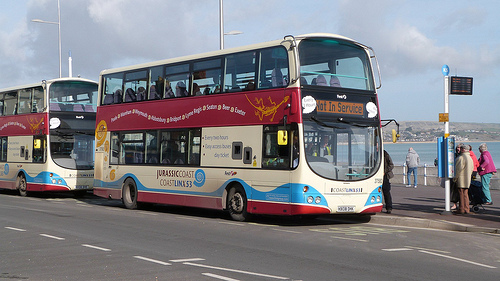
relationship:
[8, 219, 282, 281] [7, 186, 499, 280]
lines on street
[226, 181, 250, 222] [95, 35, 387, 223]
wheel on bus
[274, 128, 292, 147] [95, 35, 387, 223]
mirror on bus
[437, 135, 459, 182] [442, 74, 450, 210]
sign on pole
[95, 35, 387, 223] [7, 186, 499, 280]
bus on street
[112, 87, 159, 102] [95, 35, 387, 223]
seats on bus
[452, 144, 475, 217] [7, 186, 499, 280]
man standing next to street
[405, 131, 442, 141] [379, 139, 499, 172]
houses across water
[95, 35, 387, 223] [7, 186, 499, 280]
bus parked on street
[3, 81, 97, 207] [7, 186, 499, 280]
bus parked on street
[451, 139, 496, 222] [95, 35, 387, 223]
people waiting for bus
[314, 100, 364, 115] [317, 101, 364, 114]
not in service says not in service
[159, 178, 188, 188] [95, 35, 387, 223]
company that owns bus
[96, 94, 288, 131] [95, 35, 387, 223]
advertisement on bus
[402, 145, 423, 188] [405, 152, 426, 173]
person wearing a hoodie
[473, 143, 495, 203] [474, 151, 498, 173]
lady wearing a jacket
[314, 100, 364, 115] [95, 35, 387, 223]
not in service on bus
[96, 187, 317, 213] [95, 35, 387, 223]
stripe on bus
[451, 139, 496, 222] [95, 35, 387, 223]
people outside bus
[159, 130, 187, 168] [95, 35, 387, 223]
window on bus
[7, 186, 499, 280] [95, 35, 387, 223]
street under bus